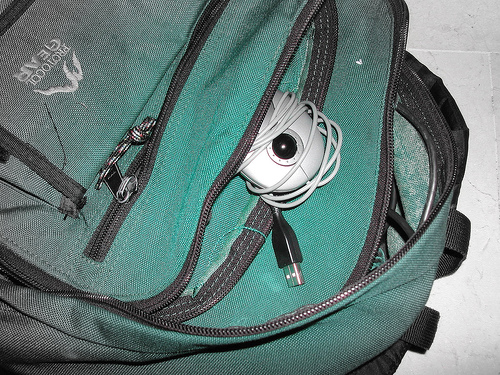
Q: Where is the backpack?
A: Floor.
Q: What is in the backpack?
A: Mouse.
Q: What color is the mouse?
A: White.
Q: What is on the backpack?
A: Zipper.